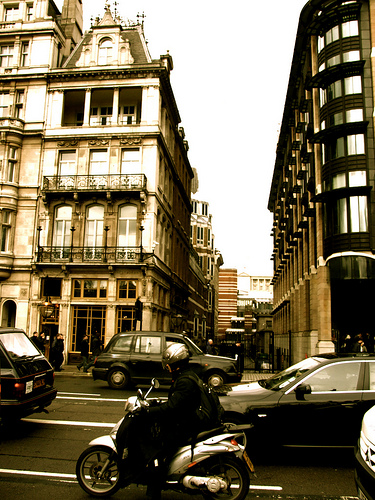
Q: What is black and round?
A: Tires.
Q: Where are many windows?
A: On buildings.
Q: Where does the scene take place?
A: On a city street.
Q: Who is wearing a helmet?
A: Motorbike rider.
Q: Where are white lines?
A: On the street.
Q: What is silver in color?
A: Motorbike.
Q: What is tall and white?
A: Building on left.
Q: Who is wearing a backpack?
A: Motorbike rider.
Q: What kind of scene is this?
A: City scene.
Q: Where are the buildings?
A: Across the street.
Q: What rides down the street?
A: Cars.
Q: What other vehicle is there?
A: Motorcycle.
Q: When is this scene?
A: Afternoon.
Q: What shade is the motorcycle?
A: Silver.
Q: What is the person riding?
A: Motorcycle.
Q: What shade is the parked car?
A: Black.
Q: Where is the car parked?
A: Street.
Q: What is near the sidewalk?
A: Buildings.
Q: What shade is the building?
A: Tan.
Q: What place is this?
A: A city.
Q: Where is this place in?
A: A city street.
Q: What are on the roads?
A: Cars and a motorbike.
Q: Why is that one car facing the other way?
A: It's parked next to a building.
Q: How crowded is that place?
A: Not much.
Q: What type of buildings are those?
A: A type of Victorian styles.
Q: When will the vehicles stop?
A: When the street light shows red.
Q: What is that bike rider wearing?
A: A dark outfit.